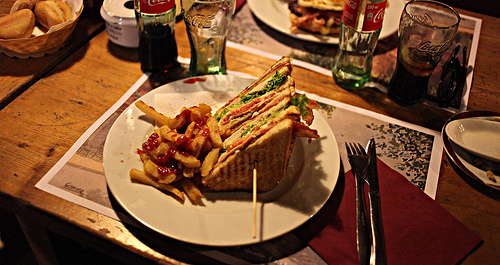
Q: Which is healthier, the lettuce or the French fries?
A: The lettuce is healthier than the French fries.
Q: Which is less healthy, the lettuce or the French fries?
A: The French fries is less healthy than the lettuce.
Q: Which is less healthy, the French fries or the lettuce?
A: The French fries is less healthy than the lettuce.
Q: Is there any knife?
A: Yes, there is a knife.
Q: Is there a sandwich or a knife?
A: Yes, there is a knife.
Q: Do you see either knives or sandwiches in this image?
A: Yes, there is a knife.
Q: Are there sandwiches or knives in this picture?
A: Yes, there is a knife.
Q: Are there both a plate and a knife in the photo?
A: Yes, there are both a knife and a plate.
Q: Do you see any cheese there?
A: No, there is no cheese.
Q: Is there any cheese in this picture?
A: No, there is no cheese.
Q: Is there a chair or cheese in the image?
A: No, there are no cheese or chairs.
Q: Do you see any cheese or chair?
A: No, there are no cheese or chairs.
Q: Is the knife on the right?
A: Yes, the knife is on the right of the image.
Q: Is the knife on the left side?
A: No, the knife is on the right of the image.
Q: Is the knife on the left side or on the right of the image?
A: The knife is on the right of the image.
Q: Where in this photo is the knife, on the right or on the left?
A: The knife is on the right of the image.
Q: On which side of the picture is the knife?
A: The knife is on the right of the image.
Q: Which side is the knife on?
A: The knife is on the right of the image.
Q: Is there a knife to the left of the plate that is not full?
A: Yes, there is a knife to the left of the plate.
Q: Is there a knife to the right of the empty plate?
A: No, the knife is to the left of the plate.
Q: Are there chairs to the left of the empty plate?
A: No, there is a knife to the left of the plate.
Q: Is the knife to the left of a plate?
A: Yes, the knife is to the left of a plate.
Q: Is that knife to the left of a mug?
A: No, the knife is to the left of a plate.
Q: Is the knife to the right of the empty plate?
A: No, the knife is to the left of the plate.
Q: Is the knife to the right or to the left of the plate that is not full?
A: The knife is to the left of the plate.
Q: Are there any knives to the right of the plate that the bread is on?
A: Yes, there is a knife to the right of the plate.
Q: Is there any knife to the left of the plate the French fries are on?
A: No, the knife is to the right of the plate.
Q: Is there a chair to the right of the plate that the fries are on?
A: No, there is a knife to the right of the plate.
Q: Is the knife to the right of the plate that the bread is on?
A: Yes, the knife is to the right of the plate.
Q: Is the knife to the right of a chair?
A: No, the knife is to the right of the plate.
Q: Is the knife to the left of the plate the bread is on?
A: No, the knife is to the right of the plate.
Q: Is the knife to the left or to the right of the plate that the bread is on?
A: The knife is to the right of the plate.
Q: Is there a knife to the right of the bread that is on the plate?
A: Yes, there is a knife to the right of the bread.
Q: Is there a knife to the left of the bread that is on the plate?
A: No, the knife is to the right of the bread.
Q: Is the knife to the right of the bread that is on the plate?
A: Yes, the knife is to the right of the bread.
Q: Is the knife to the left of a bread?
A: No, the knife is to the right of a bread.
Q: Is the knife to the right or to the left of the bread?
A: The knife is to the right of the bread.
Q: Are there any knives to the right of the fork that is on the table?
A: Yes, there is a knife to the right of the fork.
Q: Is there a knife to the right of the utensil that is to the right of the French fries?
A: Yes, there is a knife to the right of the fork.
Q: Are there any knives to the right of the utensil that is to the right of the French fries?
A: Yes, there is a knife to the right of the fork.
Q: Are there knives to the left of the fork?
A: No, the knife is to the right of the fork.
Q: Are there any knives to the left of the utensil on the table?
A: No, the knife is to the right of the fork.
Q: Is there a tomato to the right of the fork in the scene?
A: No, there is a knife to the right of the fork.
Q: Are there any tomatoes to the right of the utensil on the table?
A: No, there is a knife to the right of the fork.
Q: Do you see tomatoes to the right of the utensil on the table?
A: No, there is a knife to the right of the fork.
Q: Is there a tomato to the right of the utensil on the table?
A: No, there is a knife to the right of the fork.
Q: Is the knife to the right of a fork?
A: Yes, the knife is to the right of a fork.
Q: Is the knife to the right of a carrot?
A: No, the knife is to the right of a fork.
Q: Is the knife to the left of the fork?
A: No, the knife is to the right of the fork.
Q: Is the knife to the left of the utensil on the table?
A: No, the knife is to the right of the fork.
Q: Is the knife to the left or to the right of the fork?
A: The knife is to the right of the fork.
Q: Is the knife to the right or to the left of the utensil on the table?
A: The knife is to the right of the fork.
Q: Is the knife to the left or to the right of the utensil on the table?
A: The knife is to the right of the fork.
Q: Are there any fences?
A: No, there are no fences.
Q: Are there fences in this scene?
A: No, there are no fences.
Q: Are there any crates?
A: No, there are no crates.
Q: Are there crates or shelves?
A: No, there are no crates or shelves.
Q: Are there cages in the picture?
A: No, there are no cages.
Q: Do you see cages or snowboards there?
A: No, there are no cages or snowboards.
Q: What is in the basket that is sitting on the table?
A: The toilet roll is in the basket.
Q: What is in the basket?
A: The toilet roll is in the basket.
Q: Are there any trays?
A: No, there are no trays.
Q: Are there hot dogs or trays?
A: No, there are no trays or hot dogs.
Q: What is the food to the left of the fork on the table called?
A: The food is fries.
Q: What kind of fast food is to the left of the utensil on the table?
A: The food is fries.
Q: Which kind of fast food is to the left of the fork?
A: The food is fries.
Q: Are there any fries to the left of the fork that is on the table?
A: Yes, there are fries to the left of the fork.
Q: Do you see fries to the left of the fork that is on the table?
A: Yes, there are fries to the left of the fork.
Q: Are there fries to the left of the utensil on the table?
A: Yes, there are fries to the left of the fork.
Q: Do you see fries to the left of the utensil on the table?
A: Yes, there are fries to the left of the fork.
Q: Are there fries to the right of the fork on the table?
A: No, the fries are to the left of the fork.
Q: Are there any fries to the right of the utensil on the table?
A: No, the fries are to the left of the fork.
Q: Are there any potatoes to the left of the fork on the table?
A: No, there are fries to the left of the fork.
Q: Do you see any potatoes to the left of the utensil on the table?
A: No, there are fries to the left of the fork.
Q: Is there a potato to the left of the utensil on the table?
A: No, there are fries to the left of the fork.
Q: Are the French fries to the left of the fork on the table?
A: Yes, the French fries are to the left of the fork.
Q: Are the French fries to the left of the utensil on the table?
A: Yes, the French fries are to the left of the fork.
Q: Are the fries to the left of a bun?
A: No, the fries are to the left of the fork.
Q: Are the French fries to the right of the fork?
A: No, the French fries are to the left of the fork.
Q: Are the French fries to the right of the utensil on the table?
A: No, the French fries are to the left of the fork.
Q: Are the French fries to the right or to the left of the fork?
A: The French fries are to the left of the fork.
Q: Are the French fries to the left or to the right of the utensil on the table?
A: The French fries are to the left of the fork.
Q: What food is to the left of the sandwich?
A: The food is fries.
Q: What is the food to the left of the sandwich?
A: The food is fries.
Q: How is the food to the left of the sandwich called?
A: The food is fries.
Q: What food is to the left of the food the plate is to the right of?
A: The food is fries.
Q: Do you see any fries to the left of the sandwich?
A: Yes, there are fries to the left of the sandwich.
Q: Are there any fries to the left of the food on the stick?
A: Yes, there are fries to the left of the sandwich.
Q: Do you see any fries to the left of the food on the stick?
A: Yes, there are fries to the left of the sandwich.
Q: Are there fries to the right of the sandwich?
A: No, the fries are to the left of the sandwich.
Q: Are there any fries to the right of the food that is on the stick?
A: No, the fries are to the left of the sandwich.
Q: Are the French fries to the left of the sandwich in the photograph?
A: Yes, the French fries are to the left of the sandwich.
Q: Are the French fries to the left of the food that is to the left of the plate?
A: Yes, the French fries are to the left of the sandwich.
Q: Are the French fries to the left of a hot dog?
A: No, the French fries are to the left of the sandwich.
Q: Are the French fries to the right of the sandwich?
A: No, the French fries are to the left of the sandwich.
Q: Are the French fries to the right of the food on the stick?
A: No, the French fries are to the left of the sandwich.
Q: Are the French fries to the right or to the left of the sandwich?
A: The French fries are to the left of the sandwich.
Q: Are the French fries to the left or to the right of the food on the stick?
A: The French fries are to the left of the sandwich.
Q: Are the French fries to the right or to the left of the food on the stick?
A: The French fries are to the left of the sandwich.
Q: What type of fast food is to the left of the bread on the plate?
A: The food is fries.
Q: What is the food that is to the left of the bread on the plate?
A: The food is fries.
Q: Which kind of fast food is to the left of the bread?
A: The food is fries.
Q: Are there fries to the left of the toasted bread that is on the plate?
A: Yes, there are fries to the left of the bread.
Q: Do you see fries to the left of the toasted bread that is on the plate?
A: Yes, there are fries to the left of the bread.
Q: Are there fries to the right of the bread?
A: No, the fries are to the left of the bread.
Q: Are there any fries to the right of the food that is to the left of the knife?
A: No, the fries are to the left of the bread.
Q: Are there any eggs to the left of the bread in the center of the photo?
A: No, there are fries to the left of the bread.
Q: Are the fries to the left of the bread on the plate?
A: Yes, the fries are to the left of the bread.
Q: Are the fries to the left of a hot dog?
A: No, the fries are to the left of the bread.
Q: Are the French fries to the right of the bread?
A: No, the French fries are to the left of the bread.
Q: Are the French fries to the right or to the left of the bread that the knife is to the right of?
A: The French fries are to the left of the bread.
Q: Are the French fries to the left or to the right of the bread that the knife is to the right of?
A: The French fries are to the left of the bread.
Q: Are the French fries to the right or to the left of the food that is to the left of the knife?
A: The French fries are to the left of the bread.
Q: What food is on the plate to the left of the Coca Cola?
A: The food is fries.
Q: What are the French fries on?
A: The French fries are on the plate.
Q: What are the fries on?
A: The French fries are on the plate.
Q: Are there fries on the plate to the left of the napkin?
A: Yes, there are fries on the plate.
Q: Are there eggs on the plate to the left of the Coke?
A: No, there are fries on the plate.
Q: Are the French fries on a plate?
A: Yes, the French fries are on a plate.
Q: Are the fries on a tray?
A: No, the fries are on a plate.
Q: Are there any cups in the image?
A: Yes, there is a cup.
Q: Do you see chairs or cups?
A: Yes, there is a cup.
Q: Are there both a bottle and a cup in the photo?
A: Yes, there are both a cup and a bottle.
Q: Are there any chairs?
A: No, there are no chairs.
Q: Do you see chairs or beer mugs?
A: No, there are no chairs or beer mugs.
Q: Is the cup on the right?
A: Yes, the cup is on the right of the image.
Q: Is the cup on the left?
A: No, the cup is on the right of the image.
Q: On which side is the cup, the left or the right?
A: The cup is on the right of the image.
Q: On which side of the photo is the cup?
A: The cup is on the right of the image.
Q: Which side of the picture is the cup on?
A: The cup is on the right of the image.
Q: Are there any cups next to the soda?
A: Yes, there is a cup next to the soda.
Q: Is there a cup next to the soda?
A: Yes, there is a cup next to the soda.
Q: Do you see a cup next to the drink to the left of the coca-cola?
A: Yes, there is a cup next to the soda.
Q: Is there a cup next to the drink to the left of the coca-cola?
A: Yes, there is a cup next to the soda.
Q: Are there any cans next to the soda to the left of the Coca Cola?
A: No, there is a cup next to the soda.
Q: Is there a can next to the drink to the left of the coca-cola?
A: No, there is a cup next to the soda.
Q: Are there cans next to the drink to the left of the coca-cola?
A: No, there is a cup next to the soda.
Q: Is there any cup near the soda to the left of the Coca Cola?
A: Yes, there is a cup near the soda.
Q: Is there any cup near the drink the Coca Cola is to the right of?
A: Yes, there is a cup near the soda.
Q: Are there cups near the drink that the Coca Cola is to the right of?
A: Yes, there is a cup near the soda.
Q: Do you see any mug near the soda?
A: No, there is a cup near the soda.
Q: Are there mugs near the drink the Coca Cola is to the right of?
A: No, there is a cup near the soda.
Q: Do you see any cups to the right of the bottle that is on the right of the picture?
A: Yes, there is a cup to the right of the bottle.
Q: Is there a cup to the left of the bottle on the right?
A: No, the cup is to the right of the bottle.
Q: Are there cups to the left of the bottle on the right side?
A: No, the cup is to the right of the bottle.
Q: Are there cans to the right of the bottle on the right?
A: No, there is a cup to the right of the bottle.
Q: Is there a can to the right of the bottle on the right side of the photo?
A: No, there is a cup to the right of the bottle.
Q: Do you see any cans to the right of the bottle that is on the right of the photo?
A: No, there is a cup to the right of the bottle.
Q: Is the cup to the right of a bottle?
A: Yes, the cup is to the right of a bottle.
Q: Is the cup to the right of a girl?
A: No, the cup is to the right of a bottle.